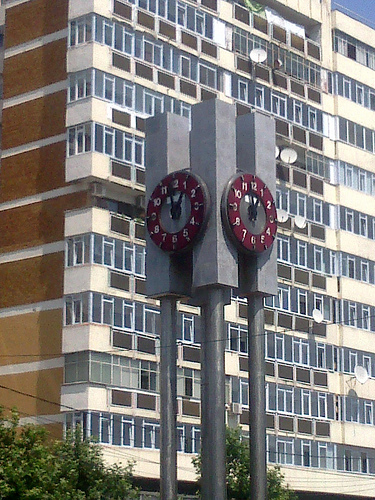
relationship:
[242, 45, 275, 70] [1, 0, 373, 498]
satellite dish on building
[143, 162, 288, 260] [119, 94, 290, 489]
clocks on tower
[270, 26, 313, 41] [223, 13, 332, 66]
cloth hanging on porch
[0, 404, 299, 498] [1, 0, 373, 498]
trees near building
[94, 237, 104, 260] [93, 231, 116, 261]
white curtain in window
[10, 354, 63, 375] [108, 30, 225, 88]
stripe on wall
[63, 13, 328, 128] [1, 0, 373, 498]
windows in a building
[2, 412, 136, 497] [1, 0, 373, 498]
trees around base of a building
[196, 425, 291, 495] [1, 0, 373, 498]
trees around base of a building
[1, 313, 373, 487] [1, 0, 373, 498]
power lines hanging off a building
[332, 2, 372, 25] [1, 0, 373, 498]
sky above building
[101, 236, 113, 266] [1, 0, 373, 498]
window on building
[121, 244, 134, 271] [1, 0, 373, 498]
window on building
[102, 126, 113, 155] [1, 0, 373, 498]
window on building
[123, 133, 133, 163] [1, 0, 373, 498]
window on building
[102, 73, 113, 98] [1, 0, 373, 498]
window on building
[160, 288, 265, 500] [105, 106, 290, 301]
iron columns holding clock tower